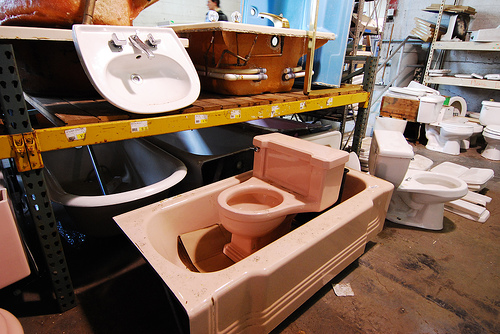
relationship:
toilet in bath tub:
[215, 132, 352, 263] [94, 128, 399, 332]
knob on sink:
[108, 29, 125, 52] [68, 17, 203, 119]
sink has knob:
[103, 53, 203, 114] [143, 22, 163, 49]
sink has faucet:
[68, 17, 203, 119] [131, 30, 156, 61]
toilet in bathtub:
[210, 123, 352, 263] [108, 165, 394, 332]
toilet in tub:
[215, 132, 352, 263] [111, 165, 393, 332]